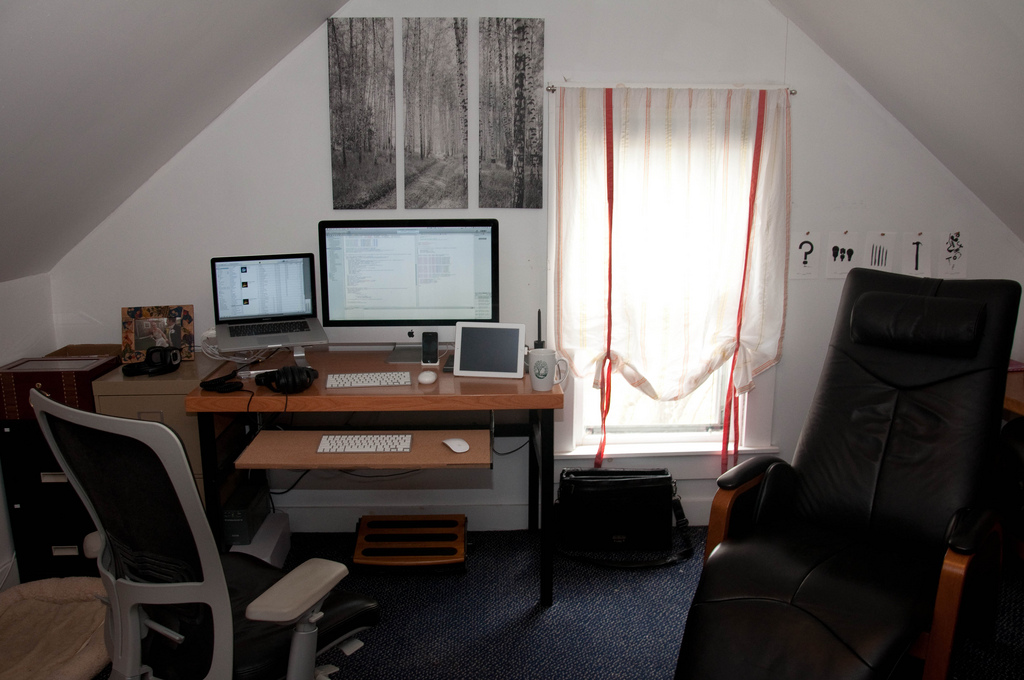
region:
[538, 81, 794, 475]
the curtain is hanging up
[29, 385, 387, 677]
the large office chair is black and gray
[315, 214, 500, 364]
the imac is large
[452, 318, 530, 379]
the ipad is white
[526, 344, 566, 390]
the white coffee mug is tall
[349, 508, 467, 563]
the foot stool is brown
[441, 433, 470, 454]
the wireless mouse is white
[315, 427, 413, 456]
the keyboard is white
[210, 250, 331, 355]
the macbook is silver and gray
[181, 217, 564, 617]
the apple products on the desk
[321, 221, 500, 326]
monitor is black and white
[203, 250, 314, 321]
monitor is black and white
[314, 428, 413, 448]
keyboard is white and small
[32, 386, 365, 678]
chair is white and black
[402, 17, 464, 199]
black and white poster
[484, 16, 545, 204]
black and white poster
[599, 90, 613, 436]
CURtain has a red stripe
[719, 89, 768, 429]
CURtain has a red stripe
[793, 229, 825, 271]
question mark on a paper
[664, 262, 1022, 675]
black leather recliner with wooden arms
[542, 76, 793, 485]
white curtain with red ties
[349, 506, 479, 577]
wooden foot rest under desk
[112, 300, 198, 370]
picture frame on filing cabinet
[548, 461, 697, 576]
black leather briefcase on floor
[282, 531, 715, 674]
dark blue carpet on floor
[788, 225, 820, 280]
black question mark hung on wall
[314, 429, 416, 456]
white keyboard on pull out tray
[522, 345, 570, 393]
white coffee mug with green drawing on front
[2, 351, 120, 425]
wooden humidor with gold embellishments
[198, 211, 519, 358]
Two computer monitors on a desk.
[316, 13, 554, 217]
Black and white art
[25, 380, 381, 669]
Computer chair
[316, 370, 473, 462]
Two keyboard and mouse sets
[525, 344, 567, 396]
A coffee cup on a desk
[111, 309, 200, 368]
A picture frame on a metal filing cabinet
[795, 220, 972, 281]
Art decor hanging on a wall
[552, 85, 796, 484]
White and red curtains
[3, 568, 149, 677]
A dog bed next to a computer desk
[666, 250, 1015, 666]
A leather office chair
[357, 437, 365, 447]
A key on a keyboard.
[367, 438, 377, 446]
A key on a keyboard.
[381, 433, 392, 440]
A key on a keyboard.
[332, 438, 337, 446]
A key on a keyboard.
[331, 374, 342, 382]
A key on a keyboard.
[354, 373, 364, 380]
A key on a keyboard.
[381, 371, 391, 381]
A key on a keyboard.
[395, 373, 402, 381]
A key on a keyboard.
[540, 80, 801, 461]
sunny window with white curtain and red drawstring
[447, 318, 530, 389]
white tablet with black screen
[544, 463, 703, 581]
black laptop carrying bag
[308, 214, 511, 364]
black computer turned on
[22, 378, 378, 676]
grey office chair with black cushions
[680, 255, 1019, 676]
wood chair with black cushions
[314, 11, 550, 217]
sepia triptych of a forest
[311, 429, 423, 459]
a white computer keyboard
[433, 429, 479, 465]
a white computer mouse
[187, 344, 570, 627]
a wood top computer desk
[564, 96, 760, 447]
a window in the room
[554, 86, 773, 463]
curtains on the window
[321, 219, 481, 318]
a computer monitor